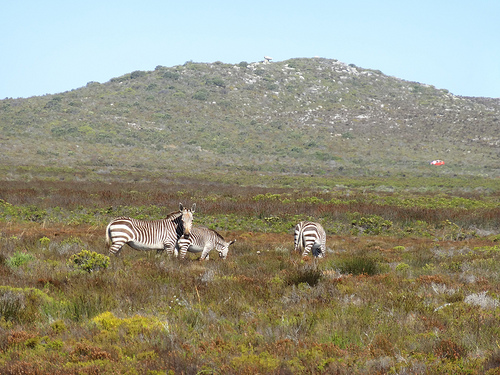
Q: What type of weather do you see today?
A: It is cloudless.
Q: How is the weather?
A: It is cloudless.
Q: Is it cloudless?
A: Yes, it is cloudless.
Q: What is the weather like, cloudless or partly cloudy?
A: It is cloudless.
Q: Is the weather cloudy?
A: No, it is cloudless.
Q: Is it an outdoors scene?
A: Yes, it is outdoors.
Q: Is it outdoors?
A: Yes, it is outdoors.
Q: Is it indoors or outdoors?
A: It is outdoors.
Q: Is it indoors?
A: No, it is outdoors.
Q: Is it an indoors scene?
A: No, it is outdoors.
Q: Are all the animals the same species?
A: No, there are both zebras and goats.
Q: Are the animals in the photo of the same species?
A: No, they are zebras and goats.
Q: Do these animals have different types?
A: Yes, they are zebras and goats.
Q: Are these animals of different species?
A: Yes, they are zebras and goats.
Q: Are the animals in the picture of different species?
A: Yes, they are zebras and goats.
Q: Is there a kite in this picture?
A: No, there are no kites.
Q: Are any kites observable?
A: No, there are no kites.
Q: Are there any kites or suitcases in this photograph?
A: No, there are no kites or suitcases.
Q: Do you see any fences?
A: No, there are no fences.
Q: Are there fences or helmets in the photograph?
A: No, there are no fences or helmets.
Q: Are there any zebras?
A: Yes, there is a zebra.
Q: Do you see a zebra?
A: Yes, there is a zebra.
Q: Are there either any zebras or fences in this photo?
A: Yes, there is a zebra.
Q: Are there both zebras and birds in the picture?
A: No, there is a zebra but no birds.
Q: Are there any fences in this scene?
A: No, there are no fences.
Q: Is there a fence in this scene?
A: No, there are no fences.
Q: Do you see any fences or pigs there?
A: No, there are no fences or pigs.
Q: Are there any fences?
A: No, there are no fences.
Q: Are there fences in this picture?
A: No, there are no fences.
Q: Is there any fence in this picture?
A: No, there are no fences.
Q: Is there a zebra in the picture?
A: Yes, there are zebras.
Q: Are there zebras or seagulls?
A: Yes, there are zebras.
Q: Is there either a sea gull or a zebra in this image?
A: Yes, there are zebras.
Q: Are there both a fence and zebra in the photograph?
A: No, there are zebras but no fences.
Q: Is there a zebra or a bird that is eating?
A: Yes, the zebras are eating.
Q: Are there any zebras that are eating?
A: Yes, there are zebras that are eating.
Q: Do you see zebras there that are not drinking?
A: Yes, there are zebras that are eating .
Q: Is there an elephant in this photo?
A: No, there are no elephants.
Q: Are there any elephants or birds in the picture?
A: No, there are no elephants or birds.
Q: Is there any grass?
A: Yes, there is grass.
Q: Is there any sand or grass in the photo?
A: Yes, there is grass.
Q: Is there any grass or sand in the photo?
A: Yes, there is grass.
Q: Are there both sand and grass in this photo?
A: No, there is grass but no sand.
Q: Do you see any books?
A: No, there are no books.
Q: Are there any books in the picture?
A: No, there are no books.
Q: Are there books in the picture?
A: No, there are no books.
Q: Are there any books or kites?
A: No, there are no books or kites.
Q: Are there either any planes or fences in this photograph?
A: No, there are no fences or planes.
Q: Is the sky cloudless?
A: Yes, the sky is cloudless.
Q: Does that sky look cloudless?
A: Yes, the sky is cloudless.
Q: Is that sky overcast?
A: No, the sky is cloudless.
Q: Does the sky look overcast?
A: No, the sky is cloudless.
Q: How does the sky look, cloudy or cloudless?
A: The sky is cloudless.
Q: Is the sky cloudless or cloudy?
A: The sky is cloudless.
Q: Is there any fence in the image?
A: No, there are no fences.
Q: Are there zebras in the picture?
A: Yes, there is a zebra.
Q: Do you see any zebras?
A: Yes, there is a zebra.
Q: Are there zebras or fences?
A: Yes, there is a zebra.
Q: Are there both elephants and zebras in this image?
A: No, there is a zebra but no elephants.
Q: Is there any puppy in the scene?
A: No, there are no puppies.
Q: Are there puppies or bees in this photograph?
A: No, there are no puppies or bees.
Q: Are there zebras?
A: Yes, there is a zebra.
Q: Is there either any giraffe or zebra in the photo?
A: Yes, there is a zebra.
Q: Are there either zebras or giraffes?
A: Yes, there is a zebra.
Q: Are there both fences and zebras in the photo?
A: No, there is a zebra but no fences.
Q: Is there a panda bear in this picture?
A: No, there are no panda bears.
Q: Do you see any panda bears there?
A: No, there are no panda bears.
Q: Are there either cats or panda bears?
A: No, there are no panda bears or cats.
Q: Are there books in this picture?
A: No, there are no books.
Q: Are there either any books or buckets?
A: No, there are no books or buckets.